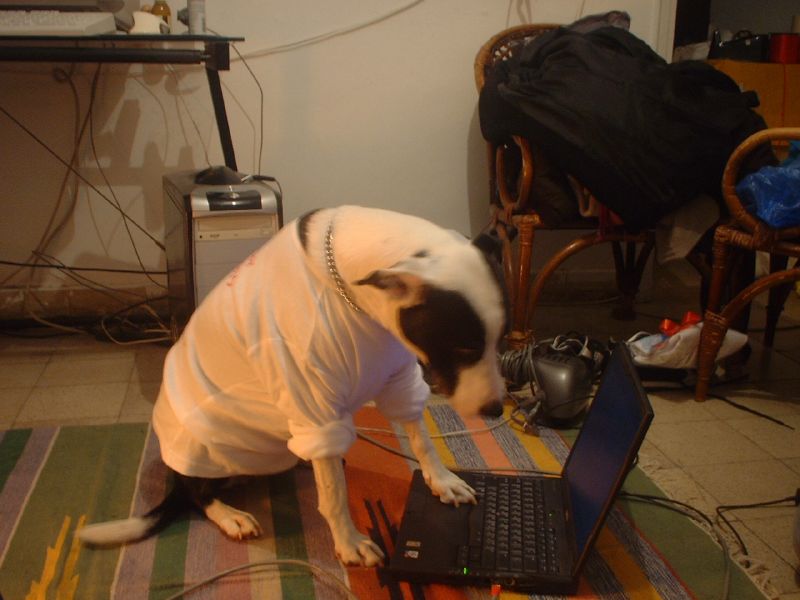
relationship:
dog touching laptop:
[149, 197, 519, 547] [376, 314, 658, 593]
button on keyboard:
[456, 555, 472, 569] [459, 458, 565, 584]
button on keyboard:
[493, 539, 507, 560] [474, 469, 542, 575]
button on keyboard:
[482, 546, 524, 557] [476, 468, 548, 565]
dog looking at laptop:
[178, 197, 468, 547] [434, 356, 647, 571]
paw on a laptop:
[394, 442, 469, 507] [389, 357, 665, 569]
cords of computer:
[659, 482, 704, 531] [406, 340, 678, 581]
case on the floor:
[166, 164, 266, 268] [82, 346, 109, 391]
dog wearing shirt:
[149, 197, 519, 547] [176, 298, 330, 447]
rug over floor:
[51, 445, 112, 504] [45, 369, 69, 402]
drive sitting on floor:
[184, 171, 255, 255] [51, 338, 135, 399]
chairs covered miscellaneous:
[498, 33, 775, 369] [502, 26, 772, 226]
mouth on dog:
[419, 363, 503, 422] [76, 206, 506, 562]